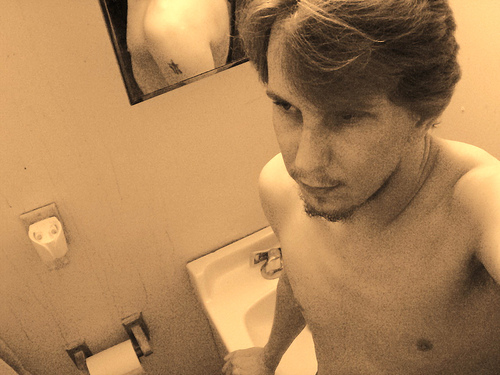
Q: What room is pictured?
A: It is a bathroom.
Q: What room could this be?
A: It is a bathroom.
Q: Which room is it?
A: It is a bathroom.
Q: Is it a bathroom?
A: Yes, it is a bathroom.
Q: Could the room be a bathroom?
A: Yes, it is a bathroom.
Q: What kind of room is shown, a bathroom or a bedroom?
A: It is a bathroom.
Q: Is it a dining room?
A: No, it is a bathroom.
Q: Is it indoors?
A: Yes, it is indoors.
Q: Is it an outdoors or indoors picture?
A: It is indoors.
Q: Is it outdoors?
A: No, it is indoors.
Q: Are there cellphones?
A: No, there are no cellphones.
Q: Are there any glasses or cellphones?
A: No, there are no cellphones or glasses.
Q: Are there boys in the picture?
A: No, there are no boys.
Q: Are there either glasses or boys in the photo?
A: No, there are no boys or glasses.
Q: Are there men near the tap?
A: Yes, there is a man near the tap.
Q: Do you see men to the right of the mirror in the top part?
A: Yes, there is a man to the right of the mirror.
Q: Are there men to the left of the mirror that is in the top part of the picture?
A: No, the man is to the right of the mirror.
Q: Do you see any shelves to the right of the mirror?
A: No, there is a man to the right of the mirror.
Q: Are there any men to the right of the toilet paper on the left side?
A: Yes, there is a man to the right of the toilet paper.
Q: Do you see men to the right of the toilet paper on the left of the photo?
A: Yes, there is a man to the right of the toilet paper.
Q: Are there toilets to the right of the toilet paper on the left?
A: No, there is a man to the right of the toilet paper.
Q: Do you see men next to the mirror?
A: Yes, there is a man next to the mirror.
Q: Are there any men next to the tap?
A: Yes, there is a man next to the tap.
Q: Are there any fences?
A: No, there are no fences.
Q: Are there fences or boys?
A: No, there are no fences or boys.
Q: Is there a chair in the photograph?
A: No, there are no chairs.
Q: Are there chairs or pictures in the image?
A: No, there are no chairs or pictures.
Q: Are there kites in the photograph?
A: No, there are no kites.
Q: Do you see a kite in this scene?
A: No, there are no kites.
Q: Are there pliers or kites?
A: No, there are no kites or pliers.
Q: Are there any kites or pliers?
A: No, there are no kites or pliers.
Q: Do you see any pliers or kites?
A: No, there are no kites or pliers.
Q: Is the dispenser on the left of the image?
A: Yes, the dispenser is on the left of the image.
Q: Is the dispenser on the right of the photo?
A: No, the dispenser is on the left of the image.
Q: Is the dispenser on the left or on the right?
A: The dispenser is on the left of the image.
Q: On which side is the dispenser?
A: The dispenser is on the left of the image.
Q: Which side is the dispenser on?
A: The dispenser is on the left of the image.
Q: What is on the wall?
A: The dispenser is on the wall.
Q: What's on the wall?
A: The dispenser is on the wall.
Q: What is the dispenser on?
A: The dispenser is on the wall.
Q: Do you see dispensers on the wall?
A: Yes, there is a dispenser on the wall.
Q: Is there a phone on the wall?
A: No, there is a dispenser on the wall.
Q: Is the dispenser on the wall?
A: Yes, the dispenser is on the wall.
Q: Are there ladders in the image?
A: No, there are no ladders.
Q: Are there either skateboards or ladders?
A: No, there are no ladders or skateboards.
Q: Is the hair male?
A: Yes, the hair is male.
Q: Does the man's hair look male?
A: Yes, the hair is male.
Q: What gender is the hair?
A: The hair is male.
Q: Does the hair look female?
A: No, the hair is male.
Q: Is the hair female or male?
A: The hair is male.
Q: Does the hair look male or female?
A: The hair is male.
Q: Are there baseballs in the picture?
A: No, there are no baseballs.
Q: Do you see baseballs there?
A: No, there are no baseballs.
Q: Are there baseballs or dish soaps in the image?
A: No, there are no baseballs or dish soaps.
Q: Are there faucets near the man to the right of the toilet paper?
A: Yes, there is a faucet near the man.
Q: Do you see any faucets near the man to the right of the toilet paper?
A: Yes, there is a faucet near the man.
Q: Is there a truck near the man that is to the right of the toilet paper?
A: No, there is a faucet near the man.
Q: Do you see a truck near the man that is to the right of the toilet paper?
A: No, there is a faucet near the man.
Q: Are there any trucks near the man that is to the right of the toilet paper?
A: No, there is a faucet near the man.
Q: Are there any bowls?
A: No, there are no bowls.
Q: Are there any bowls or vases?
A: No, there are no bowls or vases.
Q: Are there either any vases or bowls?
A: No, there are no bowls or vases.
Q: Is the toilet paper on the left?
A: Yes, the toilet paper is on the left of the image.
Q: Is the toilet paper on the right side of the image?
A: No, the toilet paper is on the left of the image.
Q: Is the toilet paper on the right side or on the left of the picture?
A: The toilet paper is on the left of the image.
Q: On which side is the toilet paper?
A: The toilet paper is on the left of the image.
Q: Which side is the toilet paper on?
A: The toilet paper is on the left of the image.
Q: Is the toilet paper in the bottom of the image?
A: Yes, the toilet paper is in the bottom of the image.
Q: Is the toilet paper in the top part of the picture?
A: No, the toilet paper is in the bottom of the image.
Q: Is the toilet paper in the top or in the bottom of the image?
A: The toilet paper is in the bottom of the image.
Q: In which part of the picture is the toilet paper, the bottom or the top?
A: The toilet paper is in the bottom of the image.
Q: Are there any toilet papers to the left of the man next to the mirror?
A: Yes, there is a toilet paper to the left of the man.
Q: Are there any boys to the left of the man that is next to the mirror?
A: No, there is a toilet paper to the left of the man.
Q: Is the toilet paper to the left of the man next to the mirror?
A: Yes, the toilet paper is to the left of the man.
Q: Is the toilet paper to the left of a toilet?
A: No, the toilet paper is to the left of the man.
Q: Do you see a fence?
A: No, there are no fences.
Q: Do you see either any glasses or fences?
A: No, there are no fences or glasses.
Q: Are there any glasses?
A: No, there are no glasses.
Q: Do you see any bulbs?
A: No, there are no bulbs.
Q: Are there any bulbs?
A: No, there are no bulbs.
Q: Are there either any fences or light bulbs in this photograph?
A: No, there are no light bulbs or fences.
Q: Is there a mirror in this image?
A: Yes, there is a mirror.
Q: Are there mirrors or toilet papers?
A: Yes, there is a mirror.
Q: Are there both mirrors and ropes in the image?
A: No, there is a mirror but no ropes.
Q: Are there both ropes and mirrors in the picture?
A: No, there is a mirror but no ropes.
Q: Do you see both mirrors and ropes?
A: No, there is a mirror but no ropes.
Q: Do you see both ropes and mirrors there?
A: No, there is a mirror but no ropes.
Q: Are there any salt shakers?
A: No, there are no salt shakers.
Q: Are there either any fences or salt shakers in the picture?
A: No, there are no salt shakers or fences.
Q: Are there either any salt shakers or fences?
A: No, there are no salt shakers or fences.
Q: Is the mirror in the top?
A: Yes, the mirror is in the top of the image.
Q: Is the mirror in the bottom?
A: No, the mirror is in the top of the image.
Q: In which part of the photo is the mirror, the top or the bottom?
A: The mirror is in the top of the image.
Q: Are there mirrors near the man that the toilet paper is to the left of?
A: Yes, there is a mirror near the man.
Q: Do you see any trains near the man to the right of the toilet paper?
A: No, there is a mirror near the man.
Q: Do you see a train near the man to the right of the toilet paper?
A: No, there is a mirror near the man.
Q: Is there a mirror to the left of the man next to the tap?
A: Yes, there is a mirror to the left of the man.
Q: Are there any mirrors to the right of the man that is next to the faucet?
A: No, the mirror is to the left of the man.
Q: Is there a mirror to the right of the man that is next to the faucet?
A: No, the mirror is to the left of the man.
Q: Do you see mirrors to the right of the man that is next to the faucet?
A: No, the mirror is to the left of the man.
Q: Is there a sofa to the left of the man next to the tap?
A: No, there is a mirror to the left of the man.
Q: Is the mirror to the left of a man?
A: Yes, the mirror is to the left of a man.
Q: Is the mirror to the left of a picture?
A: No, the mirror is to the left of a man.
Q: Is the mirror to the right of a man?
A: No, the mirror is to the left of a man.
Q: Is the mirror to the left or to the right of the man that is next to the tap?
A: The mirror is to the left of the man.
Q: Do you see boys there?
A: No, there are no boys.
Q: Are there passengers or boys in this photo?
A: No, there are no boys or passengers.